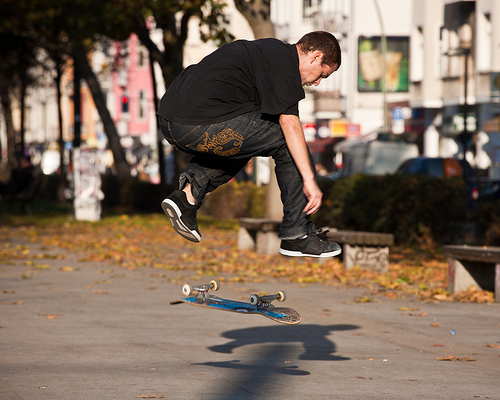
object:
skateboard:
[169, 279, 302, 326]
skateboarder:
[155, 31, 343, 259]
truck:
[182, 279, 220, 301]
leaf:
[59, 265, 74, 272]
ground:
[1, 203, 498, 399]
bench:
[236, 216, 281, 255]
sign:
[357, 35, 411, 93]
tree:
[15, 1, 134, 214]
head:
[296, 30, 341, 86]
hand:
[302, 180, 323, 215]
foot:
[161, 189, 202, 243]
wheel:
[182, 283, 193, 296]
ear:
[308, 50, 324, 64]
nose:
[313, 77, 322, 86]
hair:
[296, 31, 341, 71]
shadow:
[189, 323, 362, 375]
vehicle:
[333, 138, 421, 177]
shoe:
[278, 230, 342, 257]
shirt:
[156, 37, 306, 126]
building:
[407, 0, 500, 181]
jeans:
[155, 106, 322, 240]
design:
[196, 128, 244, 157]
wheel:
[249, 294, 260, 306]